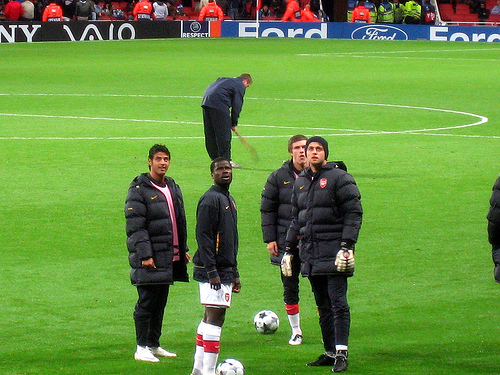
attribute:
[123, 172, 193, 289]
jacket — black 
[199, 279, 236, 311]
shorts — whtie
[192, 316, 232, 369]
socks — red , white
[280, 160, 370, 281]
jacket — nike 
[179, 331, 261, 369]
socks — white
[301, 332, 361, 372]
shoes — black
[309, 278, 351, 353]
pants — black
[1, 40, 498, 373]
grass — short , green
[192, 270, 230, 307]
shorts — white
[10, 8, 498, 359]
turf — green